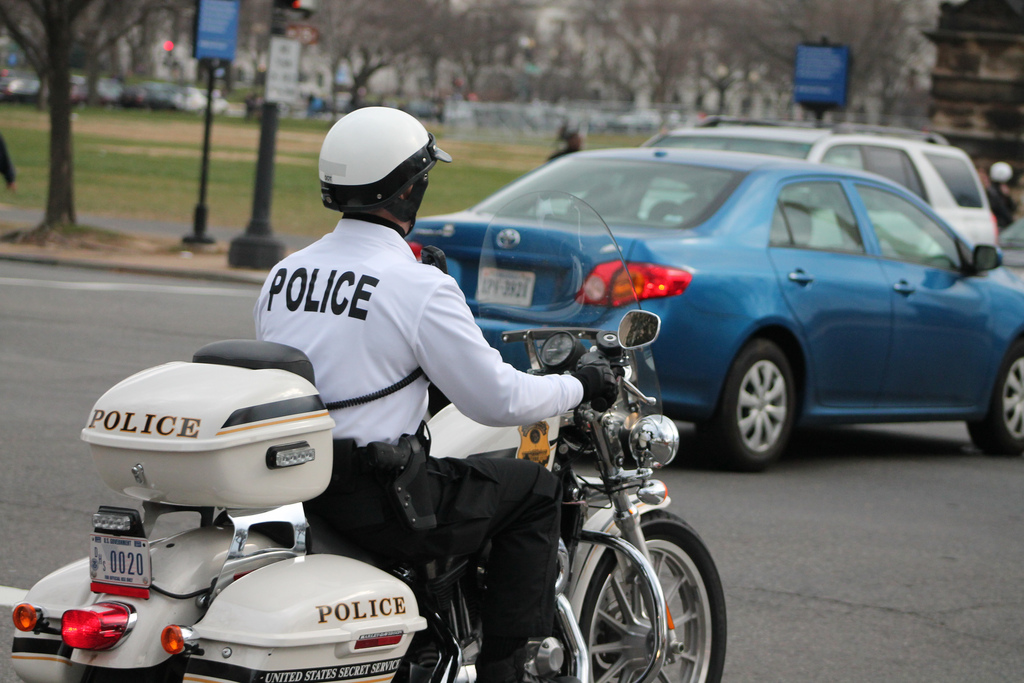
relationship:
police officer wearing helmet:
[246, 98, 618, 680] [307, 95, 457, 208]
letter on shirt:
[328, 267, 355, 317] [254, 217, 577, 440]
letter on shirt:
[267, 263, 289, 309] [252, 221, 587, 459]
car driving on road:
[414, 152, 1020, 470] [6, 254, 1020, 680]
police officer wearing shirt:
[246, 98, 618, 680] [254, 217, 577, 440]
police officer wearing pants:
[246, 98, 618, 680] [308, 442, 577, 646]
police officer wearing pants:
[246, 98, 618, 680] [310, 442, 565, 680]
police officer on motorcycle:
[246, 98, 618, 680] [6, 298, 750, 677]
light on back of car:
[583, 258, 689, 311] [414, 152, 1020, 470]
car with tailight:
[414, 142, 1022, 476] [580, 251, 689, 304]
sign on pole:
[197, 5, 237, 60] [185, 53, 222, 241]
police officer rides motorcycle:
[246, 98, 618, 680] [6, 298, 750, 677]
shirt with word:
[220, 214, 577, 530] [248, 236, 398, 353]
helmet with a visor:
[306, 96, 430, 205] [402, 124, 482, 189]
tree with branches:
[8, 0, 169, 269] [37, 13, 107, 94]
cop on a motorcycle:
[253, 72, 502, 375] [99, 318, 644, 675]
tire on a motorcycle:
[555, 491, 772, 677] [80, 318, 599, 675]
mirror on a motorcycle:
[611, 301, 661, 353] [6, 298, 750, 677]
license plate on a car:
[471, 242, 549, 320] [360, 68, 1019, 485]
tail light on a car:
[577, 251, 694, 331] [414, 91, 1007, 480]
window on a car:
[767, 158, 882, 279] [402, 74, 1012, 502]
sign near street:
[188, 2, 237, 61] [2, 175, 385, 446]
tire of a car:
[723, 337, 823, 459] [414, 91, 1007, 480]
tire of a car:
[719, 337, 806, 470] [402, 74, 1012, 502]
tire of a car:
[719, 337, 806, 470] [414, 91, 1007, 480]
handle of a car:
[782, 257, 821, 303] [414, 91, 1007, 480]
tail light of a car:
[577, 251, 695, 313] [414, 91, 1007, 480]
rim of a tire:
[734, 359, 789, 437] [710, 331, 845, 515]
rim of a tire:
[737, 357, 794, 470] [695, 314, 806, 485]